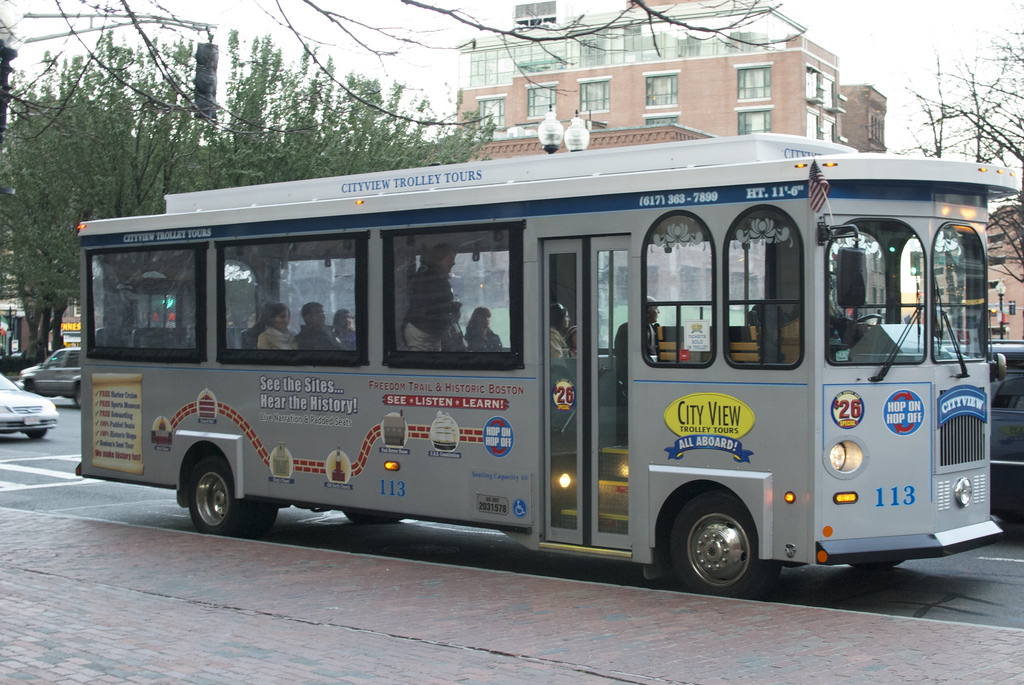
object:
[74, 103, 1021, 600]
trolley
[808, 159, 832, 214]
flag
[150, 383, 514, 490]
map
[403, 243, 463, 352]
person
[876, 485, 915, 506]
113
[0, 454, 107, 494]
crosswalk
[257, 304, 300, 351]
people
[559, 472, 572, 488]
lights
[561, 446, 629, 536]
steps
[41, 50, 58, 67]
leaves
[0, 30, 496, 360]
tree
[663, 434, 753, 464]
water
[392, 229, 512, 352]
glass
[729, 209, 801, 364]
glass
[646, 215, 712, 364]
glass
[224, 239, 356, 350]
glass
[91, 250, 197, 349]
glass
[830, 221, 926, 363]
glass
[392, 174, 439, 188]
trolley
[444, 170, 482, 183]
tours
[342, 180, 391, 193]
cityview